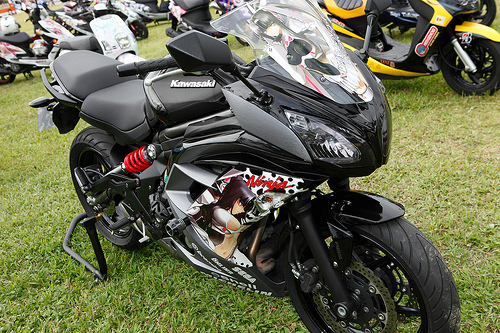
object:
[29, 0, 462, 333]
motorcycle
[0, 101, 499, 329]
grass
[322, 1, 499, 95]
motorcycle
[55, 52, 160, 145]
seat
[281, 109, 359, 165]
light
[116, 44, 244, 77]
handle bar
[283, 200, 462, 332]
wheel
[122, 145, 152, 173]
shock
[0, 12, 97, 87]
motorcycle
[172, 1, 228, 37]
motorcycle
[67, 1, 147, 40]
scooter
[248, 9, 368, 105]
girl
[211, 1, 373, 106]
windshield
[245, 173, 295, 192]
word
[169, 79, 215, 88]
word